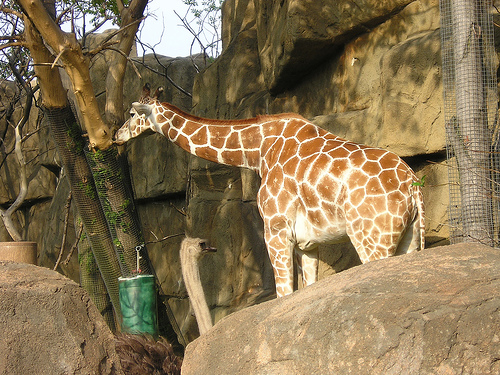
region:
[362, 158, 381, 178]
brown spot on giraffe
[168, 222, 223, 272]
ostrich head poking up behind rock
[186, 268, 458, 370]
rock in front of giraffe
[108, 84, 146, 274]
tree trunk in giraffe pen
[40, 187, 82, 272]
tree branches in pen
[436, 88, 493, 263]
wire mesh fence around tree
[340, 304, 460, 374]
cracks in rock face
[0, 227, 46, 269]
container holding tree branch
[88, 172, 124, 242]
green moss on tree trunk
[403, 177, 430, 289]
tail on the giraffe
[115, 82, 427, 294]
a giraffe eating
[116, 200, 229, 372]
an ostrich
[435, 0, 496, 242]
some chicken wire at the base of a tree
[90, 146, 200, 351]
some chicken wire at the base of a tree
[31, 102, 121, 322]
some chicken wire at the base of a tree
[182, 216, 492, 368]
a large boulder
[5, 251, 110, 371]
a large boulder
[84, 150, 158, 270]
vines growing on the tree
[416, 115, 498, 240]
some twigs in the chicken wire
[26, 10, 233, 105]
some leafless branches hanging down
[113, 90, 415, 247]
giraffe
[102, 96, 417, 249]
giraffe eating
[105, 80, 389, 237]
spotted giraffe eating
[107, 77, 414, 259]
tan and brown giraffe eating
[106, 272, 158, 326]
green bucket in encosure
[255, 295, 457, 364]
brown and gray rock in enclosure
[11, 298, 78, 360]
brown and gray rock in enclosure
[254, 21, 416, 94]
brown and gray rock in enclosure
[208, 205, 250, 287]
brown and gray rock in enclosure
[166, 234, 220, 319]
gray ostrich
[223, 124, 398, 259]
Giraffe is brown and white.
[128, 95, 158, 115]
Giraffe has white ear.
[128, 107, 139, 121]
Giraffe has dark eye.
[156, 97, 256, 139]
Giraffe has brown hair down neck.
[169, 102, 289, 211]
Giraffe has long neck.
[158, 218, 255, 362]
Ostrich standing near large rock.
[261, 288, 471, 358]
Large gray rock in front of animals.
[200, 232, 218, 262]
Ostrich has black beak.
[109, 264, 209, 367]
Green container near tree.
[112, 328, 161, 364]
Ostrich has brown feathers.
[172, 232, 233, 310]
head of ostrich facing right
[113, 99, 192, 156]
head of giraffee facing left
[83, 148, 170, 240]
green leaves inside of fencing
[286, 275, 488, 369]
large brown rock in front right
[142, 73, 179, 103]
horns located ontop of giraffee's head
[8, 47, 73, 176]
Dead grey trees with no leaves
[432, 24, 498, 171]
Tree wrapped in silver metal fencing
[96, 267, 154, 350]
Green item wrapped around tree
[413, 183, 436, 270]
tail of giraffee hanging down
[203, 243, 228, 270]
orange beak of ostrich